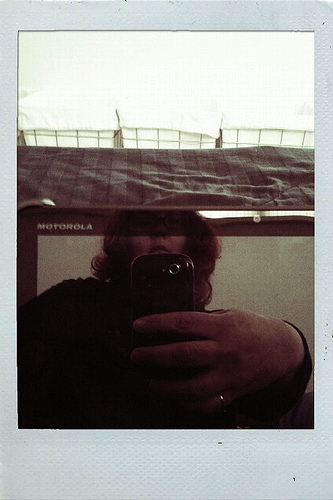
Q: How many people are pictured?
A: One.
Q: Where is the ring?
A: On the pinkie.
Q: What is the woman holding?
A: A phone.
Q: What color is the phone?
A: Black.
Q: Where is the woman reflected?
A: On a screen.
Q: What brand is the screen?
A: Motorola.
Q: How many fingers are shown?
A: Four.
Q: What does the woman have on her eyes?
A: Glasses.